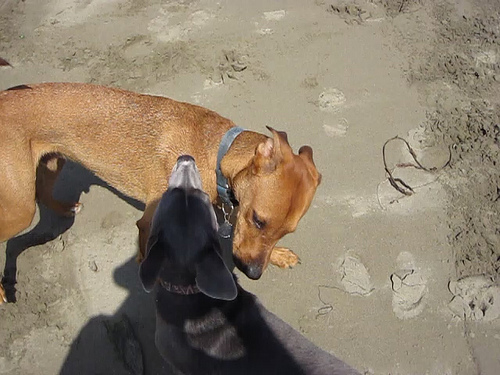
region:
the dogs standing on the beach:
[3, 79, 341, 374]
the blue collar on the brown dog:
[214, 119, 236, 247]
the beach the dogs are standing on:
[1, 1, 493, 371]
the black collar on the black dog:
[158, 272, 197, 302]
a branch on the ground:
[379, 132, 441, 197]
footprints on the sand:
[333, 242, 426, 320]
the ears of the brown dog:
[258, 121, 317, 173]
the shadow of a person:
[63, 189, 298, 374]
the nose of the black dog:
[168, 153, 193, 168]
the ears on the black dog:
[133, 233, 240, 310]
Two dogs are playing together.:
[1, 78, 357, 373]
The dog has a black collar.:
[211, 123, 246, 210]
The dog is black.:
[129, 150, 361, 372]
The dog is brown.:
[0, 80, 331, 308]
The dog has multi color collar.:
[158, 276, 198, 301]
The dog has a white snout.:
[166, 149, 205, 189]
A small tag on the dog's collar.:
[215, 215, 233, 235]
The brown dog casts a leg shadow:
[3, 187, 86, 307]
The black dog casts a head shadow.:
[52, 265, 169, 373]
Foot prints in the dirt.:
[323, 241, 437, 327]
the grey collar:
[221, 135, 236, 151]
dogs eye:
[247, 211, 265, 230]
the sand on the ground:
[319, 59, 384, 94]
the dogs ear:
[267, 124, 294, 161]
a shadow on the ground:
[42, 204, 72, 234]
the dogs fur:
[38, 102, 133, 127]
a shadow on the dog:
[167, 229, 201, 261]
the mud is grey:
[433, 36, 488, 103]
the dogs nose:
[249, 262, 260, 278]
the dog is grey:
[199, 324, 244, 363]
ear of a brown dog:
[253, 126, 294, 164]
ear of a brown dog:
[295, 142, 326, 180]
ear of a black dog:
[191, 242, 240, 309]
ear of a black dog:
[135, 237, 167, 297]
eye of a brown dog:
[248, 209, 268, 234]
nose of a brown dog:
[245, 259, 269, 283]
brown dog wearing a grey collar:
[0, 82, 337, 314]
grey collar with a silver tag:
[212, 121, 257, 246]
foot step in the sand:
[385, 249, 433, 326]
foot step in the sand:
[335, 249, 375, 302]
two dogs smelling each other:
[3, 37, 388, 354]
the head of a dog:
[229, 120, 329, 287]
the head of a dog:
[131, 150, 236, 306]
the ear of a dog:
[252, 123, 296, 172]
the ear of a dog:
[290, 143, 327, 188]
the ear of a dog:
[134, 240, 169, 292]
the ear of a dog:
[190, 246, 237, 301]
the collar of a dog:
[150, 273, 225, 300]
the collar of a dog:
[213, 115, 243, 208]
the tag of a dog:
[214, 205, 239, 242]